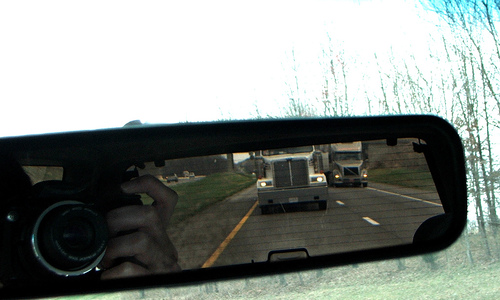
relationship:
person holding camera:
[165, 254, 177, 266] [16, 196, 102, 267]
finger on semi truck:
[124, 176, 166, 197] [257, 157, 346, 206]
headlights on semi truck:
[316, 177, 323, 183] [257, 157, 346, 206]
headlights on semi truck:
[334, 174, 341, 178] [331, 146, 371, 189]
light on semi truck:
[361, 169, 376, 181] [257, 157, 346, 206]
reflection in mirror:
[148, 179, 328, 230] [31, 151, 449, 225]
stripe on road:
[233, 216, 252, 232] [259, 224, 353, 243]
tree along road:
[229, 153, 233, 170] [259, 224, 353, 243]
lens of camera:
[69, 229, 84, 240] [16, 196, 102, 267]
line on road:
[338, 201, 343, 207] [259, 224, 353, 243]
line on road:
[366, 218, 398, 243] [259, 224, 353, 243]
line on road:
[384, 189, 413, 200] [259, 224, 353, 243]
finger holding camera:
[145, 183, 166, 197] [16, 196, 102, 267]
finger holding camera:
[126, 212, 141, 218] [16, 196, 102, 267]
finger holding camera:
[124, 241, 137, 250] [16, 196, 102, 267]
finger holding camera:
[118, 269, 129, 273] [16, 196, 102, 267]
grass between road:
[169, 172, 254, 219] [259, 224, 353, 243]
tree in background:
[177, 163, 197, 170] [216, 160, 222, 163]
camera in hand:
[16, 196, 102, 267] [135, 182, 176, 272]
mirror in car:
[31, 151, 449, 225] [165, 176, 182, 182]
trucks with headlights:
[249, 148, 326, 215] [255, 175, 327, 190]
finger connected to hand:
[104, 264, 147, 278] [106, 177, 181, 284]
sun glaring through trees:
[280, 3, 367, 57] [348, 19, 478, 92]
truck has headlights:
[251, 151, 329, 206] [250, 178, 341, 194]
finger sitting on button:
[124, 176, 166, 197] [117, 190, 133, 196]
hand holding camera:
[98, 171, 183, 280] [5, 174, 143, 281]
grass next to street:
[188, 172, 240, 205] [163, 162, 326, 222]